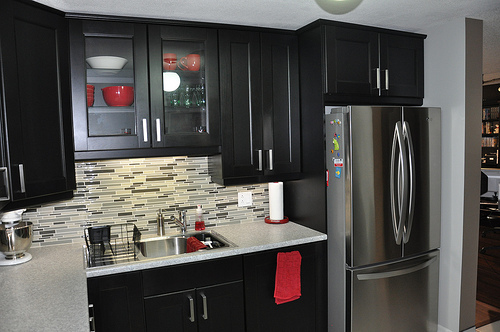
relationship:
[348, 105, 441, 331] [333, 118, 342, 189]
refrigerator has magnets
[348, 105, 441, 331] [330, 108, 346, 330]
refrigerator has side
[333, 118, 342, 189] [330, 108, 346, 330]
magnets on side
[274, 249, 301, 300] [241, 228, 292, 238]
towel below countertop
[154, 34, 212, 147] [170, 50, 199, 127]
cabinet has glass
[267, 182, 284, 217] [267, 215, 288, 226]
paper towels on holder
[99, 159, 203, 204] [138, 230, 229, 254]
wall behind sink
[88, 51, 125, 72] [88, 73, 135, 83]
bowl on shelf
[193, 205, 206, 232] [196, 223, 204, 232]
bottle has soap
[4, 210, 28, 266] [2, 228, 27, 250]
mixer has bowl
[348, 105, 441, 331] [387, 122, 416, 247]
refrigerator have handles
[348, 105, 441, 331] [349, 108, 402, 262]
refrigerator has door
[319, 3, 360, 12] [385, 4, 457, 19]
ceiling light on ceiling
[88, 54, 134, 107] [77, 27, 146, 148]
dishes behind door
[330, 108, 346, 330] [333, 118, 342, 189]
side has magnets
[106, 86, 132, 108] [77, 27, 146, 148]
bowl in cabinet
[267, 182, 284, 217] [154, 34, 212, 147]
paper towels under cabinet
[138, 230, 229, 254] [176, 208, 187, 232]
sink has faucet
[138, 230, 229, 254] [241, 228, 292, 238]
sink on countertop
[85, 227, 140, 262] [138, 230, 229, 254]
drainer near sink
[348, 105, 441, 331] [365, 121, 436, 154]
refrigerator has doors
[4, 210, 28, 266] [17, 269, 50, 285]
mixer on cabinet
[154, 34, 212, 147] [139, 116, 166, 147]
cabinet has handles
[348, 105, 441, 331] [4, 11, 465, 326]
refrigerator in kitchen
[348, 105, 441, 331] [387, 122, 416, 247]
refrigerator has handles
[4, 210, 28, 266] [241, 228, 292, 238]
mixer on countertop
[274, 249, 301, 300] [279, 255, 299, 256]
towel on handle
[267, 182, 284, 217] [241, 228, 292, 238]
paper towels in countertop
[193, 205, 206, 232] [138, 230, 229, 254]
detergent near sink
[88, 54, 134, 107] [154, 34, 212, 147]
dishes in cabinet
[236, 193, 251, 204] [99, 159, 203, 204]
outlet on wall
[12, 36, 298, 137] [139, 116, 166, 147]
cabinets have handles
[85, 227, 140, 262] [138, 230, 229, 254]
drainer in sink